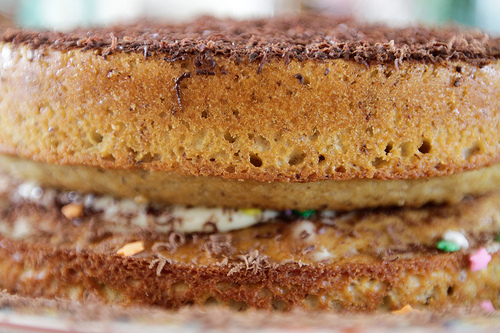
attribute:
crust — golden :
[37, 51, 219, 140]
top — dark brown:
[4, 10, 493, 64]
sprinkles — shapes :
[284, 197, 499, 317]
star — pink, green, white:
[433, 225, 493, 277]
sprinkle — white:
[441, 227, 468, 252]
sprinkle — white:
[292, 220, 314, 236]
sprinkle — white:
[486, 241, 498, 251]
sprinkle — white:
[307, 244, 333, 259]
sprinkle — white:
[321, 211, 336, 224]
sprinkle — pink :
[469, 254, 488, 271]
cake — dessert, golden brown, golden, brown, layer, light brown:
[2, 25, 497, 329]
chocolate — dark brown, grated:
[151, 4, 491, 74]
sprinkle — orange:
[59, 195, 83, 222]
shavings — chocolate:
[234, 247, 263, 273]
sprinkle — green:
[432, 236, 467, 257]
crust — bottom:
[228, 247, 468, 331]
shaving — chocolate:
[1, 172, 489, 273]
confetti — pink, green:
[419, 206, 493, 275]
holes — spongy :
[6, 241, 494, 318]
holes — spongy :
[3, 82, 496, 182]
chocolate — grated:
[2, 180, 498, 275]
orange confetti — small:
[117, 239, 144, 259]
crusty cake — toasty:
[15, 42, 495, 301]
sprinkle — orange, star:
[108, 232, 153, 266]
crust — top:
[1, 10, 483, 73]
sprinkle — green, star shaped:
[438, 239, 460, 252]